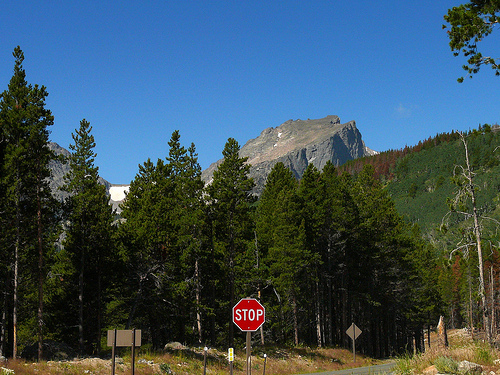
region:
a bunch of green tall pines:
[0, 49, 430, 363]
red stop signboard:
[234, 298, 264, 333]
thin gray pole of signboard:
[242, 333, 253, 373]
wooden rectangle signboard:
[107, 327, 143, 374]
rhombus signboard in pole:
[345, 319, 362, 341]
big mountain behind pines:
[182, 113, 367, 190]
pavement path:
[334, 336, 425, 373]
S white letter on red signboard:
[230, 308, 244, 325]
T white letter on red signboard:
[238, 306, 250, 323]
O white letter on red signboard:
[247, 308, 257, 325]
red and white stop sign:
[232, 294, 273, 335]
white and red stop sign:
[222, 297, 268, 337]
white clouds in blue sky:
[37, 11, 64, 49]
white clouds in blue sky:
[207, 24, 242, 62]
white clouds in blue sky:
[333, 46, 386, 87]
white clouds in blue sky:
[407, 55, 440, 116]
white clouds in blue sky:
[111, 57, 157, 94]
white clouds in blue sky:
[215, 27, 266, 68]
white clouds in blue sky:
[281, 37, 325, 82]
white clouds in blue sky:
[134, 37, 174, 75]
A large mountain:
[35, 113, 370, 243]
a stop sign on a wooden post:
[230, 295, 263, 332]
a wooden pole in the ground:
[243, 330, 250, 372]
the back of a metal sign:
[102, 325, 142, 346]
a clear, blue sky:
[0, 1, 495, 182]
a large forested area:
[0, 45, 497, 353]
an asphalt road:
[306, 360, 407, 372]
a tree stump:
[432, 313, 447, 343]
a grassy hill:
[0, 342, 372, 372]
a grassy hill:
[390, 328, 498, 373]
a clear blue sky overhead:
[51, 12, 437, 109]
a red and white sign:
[219, 294, 271, 334]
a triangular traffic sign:
[343, 312, 368, 360]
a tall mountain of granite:
[234, 112, 359, 179]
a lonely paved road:
[340, 363, 382, 373]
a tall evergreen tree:
[9, 48, 49, 345]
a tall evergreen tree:
[64, 113, 109, 350]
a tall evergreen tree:
[120, 162, 186, 344]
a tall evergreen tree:
[213, 148, 261, 310]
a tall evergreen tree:
[260, 171, 305, 338]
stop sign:
[229, 296, 271, 338]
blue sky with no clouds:
[41, 18, 81, 51]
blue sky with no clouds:
[102, 36, 130, 52]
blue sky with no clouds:
[174, 41, 218, 65]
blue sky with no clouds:
[125, 83, 170, 133]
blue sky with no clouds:
[243, 33, 275, 65]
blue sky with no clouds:
[368, 26, 393, 54]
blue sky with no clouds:
[229, 53, 267, 77]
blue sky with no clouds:
[356, 50, 385, 77]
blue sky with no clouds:
[186, 16, 244, 70]